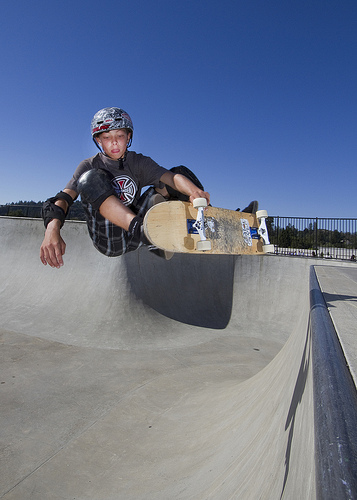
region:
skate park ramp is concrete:
[51, 323, 356, 494]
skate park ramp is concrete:
[84, 365, 270, 437]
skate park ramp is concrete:
[81, 378, 312, 497]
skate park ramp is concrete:
[110, 357, 334, 495]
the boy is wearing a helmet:
[64, 84, 163, 174]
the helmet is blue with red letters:
[64, 91, 154, 182]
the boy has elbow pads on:
[34, 165, 102, 284]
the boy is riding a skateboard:
[13, 86, 305, 287]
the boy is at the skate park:
[21, 5, 310, 422]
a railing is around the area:
[280, 190, 355, 247]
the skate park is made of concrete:
[40, 379, 252, 497]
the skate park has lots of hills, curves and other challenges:
[91, 263, 308, 439]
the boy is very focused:
[74, 97, 155, 188]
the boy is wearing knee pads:
[75, 168, 244, 269]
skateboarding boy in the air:
[34, 93, 286, 273]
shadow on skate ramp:
[285, 282, 347, 417]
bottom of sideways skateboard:
[163, 195, 282, 258]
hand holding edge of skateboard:
[185, 188, 215, 209]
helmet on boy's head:
[87, 105, 133, 157]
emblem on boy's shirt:
[106, 172, 139, 213]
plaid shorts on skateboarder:
[81, 201, 134, 258]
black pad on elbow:
[39, 185, 75, 232]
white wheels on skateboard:
[192, 195, 212, 256]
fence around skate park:
[279, 209, 347, 259]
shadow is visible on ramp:
[259, 330, 342, 492]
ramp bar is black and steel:
[297, 340, 356, 481]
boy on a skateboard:
[10, 73, 297, 278]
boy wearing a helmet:
[81, 96, 153, 159]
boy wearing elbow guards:
[30, 187, 77, 229]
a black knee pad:
[73, 164, 124, 211]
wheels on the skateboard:
[188, 196, 214, 254]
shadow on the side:
[259, 291, 315, 476]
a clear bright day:
[9, 6, 349, 485]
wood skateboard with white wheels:
[141, 197, 275, 254]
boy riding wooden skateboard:
[40, 106, 273, 269]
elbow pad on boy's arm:
[39, 190, 72, 228]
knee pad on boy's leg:
[74, 167, 118, 216]